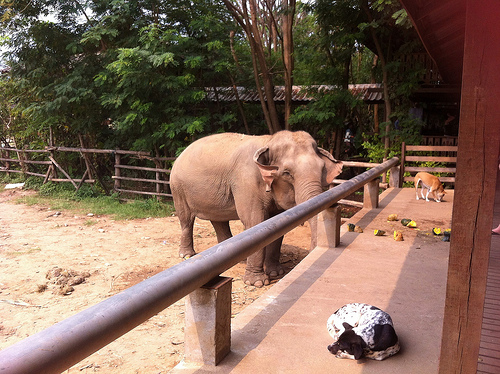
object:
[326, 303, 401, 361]
dog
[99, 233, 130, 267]
ground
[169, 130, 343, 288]
elephant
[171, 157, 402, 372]
front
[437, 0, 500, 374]
pillar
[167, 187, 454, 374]
patio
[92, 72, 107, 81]
leaves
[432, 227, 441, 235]
sliced fruit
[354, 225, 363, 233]
sliced fruit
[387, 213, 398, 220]
sliced fruit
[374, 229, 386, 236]
sliced fruit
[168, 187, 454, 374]
deck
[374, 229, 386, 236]
fruit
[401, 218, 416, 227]
fruit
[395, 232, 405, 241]
fruit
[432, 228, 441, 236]
fruit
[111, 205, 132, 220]
grass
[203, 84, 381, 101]
roof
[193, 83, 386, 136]
building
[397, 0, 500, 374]
building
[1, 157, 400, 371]
pole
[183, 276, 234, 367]
pillars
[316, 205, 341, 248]
pillars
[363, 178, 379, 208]
pillars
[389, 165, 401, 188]
pillars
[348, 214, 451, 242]
food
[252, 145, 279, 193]
ear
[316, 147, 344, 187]
ear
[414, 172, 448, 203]
dog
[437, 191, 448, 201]
head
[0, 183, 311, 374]
dirt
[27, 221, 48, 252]
ground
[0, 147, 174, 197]
wood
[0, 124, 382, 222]
fence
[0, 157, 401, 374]
pen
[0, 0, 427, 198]
trees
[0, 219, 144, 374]
surface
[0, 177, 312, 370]
enclosure